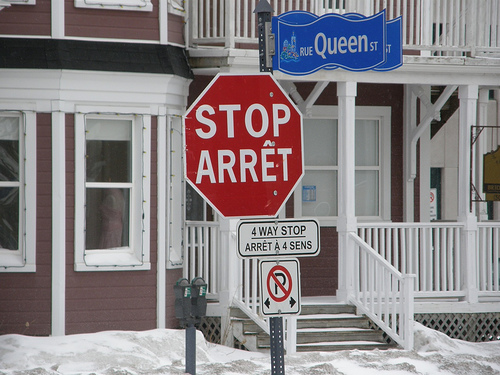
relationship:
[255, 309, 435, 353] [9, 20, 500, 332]
steps at front of building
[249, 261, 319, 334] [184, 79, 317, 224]
no parking sign below stop sign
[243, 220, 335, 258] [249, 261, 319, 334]
4-way stop sign above no parking sign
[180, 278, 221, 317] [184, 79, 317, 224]
parking meters near stop sign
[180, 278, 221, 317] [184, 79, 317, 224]
parking meters behind stop sign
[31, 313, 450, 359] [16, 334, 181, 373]
snow covers ground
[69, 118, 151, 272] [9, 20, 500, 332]
window on house